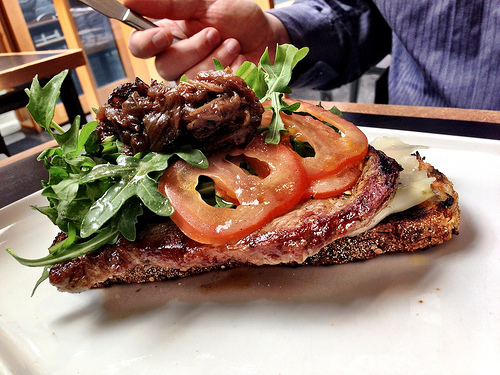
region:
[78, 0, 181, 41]
a metal silver colored butter knife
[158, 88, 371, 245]
three slices of red tomatoes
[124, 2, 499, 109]
person wearing a blue shirt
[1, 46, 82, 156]
glass top wooden framed table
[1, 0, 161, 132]
wooden doors with glass panels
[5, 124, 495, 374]
white dish of food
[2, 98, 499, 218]
table in front of a person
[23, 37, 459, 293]
greens on a pile of food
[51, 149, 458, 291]
brown toast with some black spots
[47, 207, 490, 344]
shadows on a white plate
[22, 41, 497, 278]
Food stacked on a plate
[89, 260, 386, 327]
Shadow on the plate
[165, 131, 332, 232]
Tomato slices on the meat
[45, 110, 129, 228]
Lettuce leaves on the meat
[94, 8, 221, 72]
Man holding a knife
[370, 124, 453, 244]
Cheese on top of meat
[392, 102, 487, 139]
The table is multicolored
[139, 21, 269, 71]
Man has clean nails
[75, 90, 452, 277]
The meat is grilled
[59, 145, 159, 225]
The lettuce is green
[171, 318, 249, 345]
this is a plate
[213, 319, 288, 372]
the plate is white in color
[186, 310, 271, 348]
the plate is clean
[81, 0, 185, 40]
this is a knife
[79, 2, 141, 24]
the knife is metallic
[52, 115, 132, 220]
these are some leaves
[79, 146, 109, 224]
the leaves are green in color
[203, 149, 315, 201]
these are sliced tomatoes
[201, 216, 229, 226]
the tomatoes are red in color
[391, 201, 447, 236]
this is some meat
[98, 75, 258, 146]
some mushrooms on the top of the sandwich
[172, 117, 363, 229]
a few slices of tomato on top of the bacon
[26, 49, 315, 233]
the lettuce between the onions and tomatoes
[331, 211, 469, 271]
sone if the bread under the food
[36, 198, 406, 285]
a slice of meat under the veggies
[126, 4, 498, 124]
a person sitting at the table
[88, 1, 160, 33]
the knife in the man's hand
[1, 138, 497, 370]
the plate that the food is on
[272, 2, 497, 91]
the blue shirt the man has on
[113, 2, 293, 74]
the man's hand with the fork in it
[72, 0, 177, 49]
the silver knife in the hand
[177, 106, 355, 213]
tomatoe slices on the meat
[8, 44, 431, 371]
the meat dish on the plate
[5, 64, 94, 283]
the green dressings on the meat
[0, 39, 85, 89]
the table top by the patron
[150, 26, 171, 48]
the finger nail of the finger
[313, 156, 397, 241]
the char on the meat patty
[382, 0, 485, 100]
the blue stripes on the shirt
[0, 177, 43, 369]
the white square palte on the table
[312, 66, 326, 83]
the button on the mans sleeve